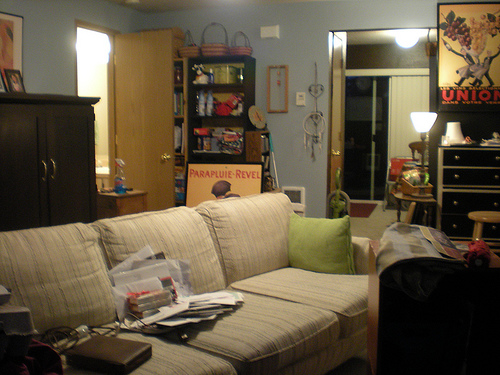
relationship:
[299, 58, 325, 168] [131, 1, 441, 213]
dream catcher hanging on wall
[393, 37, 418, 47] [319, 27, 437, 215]
globe in hallway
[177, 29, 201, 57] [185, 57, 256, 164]
basket on bookshelf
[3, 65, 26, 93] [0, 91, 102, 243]
frame on amoire